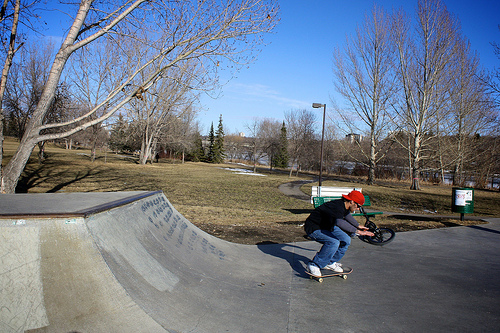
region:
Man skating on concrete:
[307, 192, 364, 279]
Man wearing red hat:
[341, 185, 368, 217]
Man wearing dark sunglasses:
[348, 197, 365, 212]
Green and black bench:
[312, 190, 385, 217]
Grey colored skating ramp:
[1, 181, 496, 328]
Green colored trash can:
[451, 183, 475, 222]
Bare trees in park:
[56, 0, 276, 168]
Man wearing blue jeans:
[312, 227, 351, 268]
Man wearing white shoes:
[305, 262, 345, 278]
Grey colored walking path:
[278, 178, 305, 198]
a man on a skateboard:
[297, 177, 372, 285]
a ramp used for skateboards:
[5, 146, 366, 318]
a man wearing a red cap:
[293, 167, 370, 291]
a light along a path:
[305, 91, 331, 196]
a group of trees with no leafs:
[333, 0, 476, 179]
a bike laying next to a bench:
[345, 193, 400, 254]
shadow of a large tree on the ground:
[20, 123, 137, 200]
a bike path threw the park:
[275, 160, 496, 232]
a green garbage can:
[447, 174, 479, 224]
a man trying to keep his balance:
[301, 160, 373, 296]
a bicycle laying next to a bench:
[346, 199, 405, 252]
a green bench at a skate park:
[309, 193, 380, 230]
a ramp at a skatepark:
[48, 177, 473, 331]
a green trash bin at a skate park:
[442, 180, 478, 224]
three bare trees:
[334, 7, 487, 184]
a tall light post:
[304, 97, 339, 183]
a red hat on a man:
[340, 188, 373, 208]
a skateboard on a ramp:
[277, 183, 379, 291]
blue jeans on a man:
[301, 214, 362, 274]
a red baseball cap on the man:
[340, 185, 367, 205]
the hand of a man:
[363, 226, 378, 241]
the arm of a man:
[324, 202, 365, 235]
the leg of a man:
[303, 220, 341, 267]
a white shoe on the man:
[303, 259, 322, 279]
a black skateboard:
[298, 256, 357, 283]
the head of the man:
[338, 186, 370, 212]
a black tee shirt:
[298, 195, 349, 237]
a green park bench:
[311, 190, 386, 219]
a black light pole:
[309, 96, 332, 188]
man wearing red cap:
[340, 187, 367, 212]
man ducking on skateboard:
[297, 188, 362, 279]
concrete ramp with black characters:
[137, 185, 242, 286]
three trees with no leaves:
[335, 1, 485, 189]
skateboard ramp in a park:
[0, 181, 492, 324]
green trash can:
[445, 181, 476, 216]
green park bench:
[311, 193, 382, 220]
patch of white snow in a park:
[222, 160, 272, 181]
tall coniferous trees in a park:
[210, 111, 290, 171]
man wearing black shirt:
[302, 186, 377, 246]